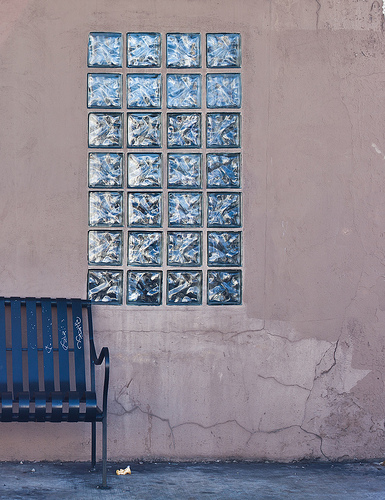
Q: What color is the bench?
A: Black.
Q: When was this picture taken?
A: Daytime.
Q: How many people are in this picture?
A: None.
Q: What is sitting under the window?
A: Bench.